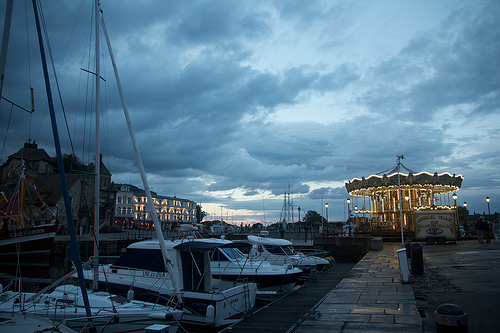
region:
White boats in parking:
[0, 228, 335, 330]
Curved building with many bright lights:
[110, 188, 200, 235]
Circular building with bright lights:
[343, 155, 463, 242]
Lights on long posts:
[322, 196, 354, 246]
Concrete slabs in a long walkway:
[287, 238, 422, 330]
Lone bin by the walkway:
[426, 301, 471, 331]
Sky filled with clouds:
[0, 1, 498, 226]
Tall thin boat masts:
[0, 0, 187, 312]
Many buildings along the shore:
[0, 139, 499, 238]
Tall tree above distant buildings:
[301, 208, 325, 235]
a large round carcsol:
[328, 136, 498, 259]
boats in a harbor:
[48, 194, 355, 327]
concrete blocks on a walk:
[346, 257, 392, 330]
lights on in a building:
[103, 190, 195, 232]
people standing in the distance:
[461, 200, 492, 246]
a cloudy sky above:
[217, 21, 365, 213]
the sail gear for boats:
[13, 1, 200, 314]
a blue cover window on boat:
[98, 243, 190, 273]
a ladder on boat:
[230, 273, 262, 318]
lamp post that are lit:
[307, 188, 498, 210]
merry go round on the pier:
[340, 151, 463, 243]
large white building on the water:
[107, 188, 197, 233]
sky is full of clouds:
[0, 3, 497, 210]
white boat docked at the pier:
[241, 228, 333, 273]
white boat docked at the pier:
[114, 232, 309, 285]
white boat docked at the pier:
[62, 227, 271, 322]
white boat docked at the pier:
[7, 279, 194, 331]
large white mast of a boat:
[86, 4, 111, 284]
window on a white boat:
[262, 242, 300, 257]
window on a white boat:
[206, 244, 243, 264]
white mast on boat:
[87, 11, 168, 279]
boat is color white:
[67, 252, 265, 320]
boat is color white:
[241, 230, 333, 272]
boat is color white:
[196, 234, 309, 282]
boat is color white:
[0, 287, 188, 327]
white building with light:
[108, 185, 204, 230]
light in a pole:
[322, 197, 334, 225]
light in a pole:
[483, 191, 493, 213]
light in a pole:
[450, 188, 460, 210]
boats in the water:
[8, 216, 330, 331]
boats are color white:
[3, 218, 328, 330]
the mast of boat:
[84, 5, 184, 307]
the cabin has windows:
[191, 232, 250, 266]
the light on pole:
[322, 199, 332, 227]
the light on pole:
[482, 192, 495, 216]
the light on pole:
[342, 196, 355, 221]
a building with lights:
[111, 187, 203, 228]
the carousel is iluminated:
[341, 150, 474, 237]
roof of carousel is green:
[333, 150, 465, 223]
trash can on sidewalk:
[389, 235, 430, 290]